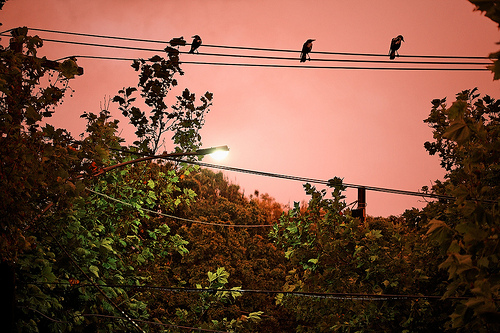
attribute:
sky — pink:
[94, 17, 479, 186]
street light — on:
[101, 144, 229, 171]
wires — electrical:
[226, 44, 262, 66]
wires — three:
[3, 26, 498, 84]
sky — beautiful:
[0, 0, 499, 217]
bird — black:
[387, 33, 404, 60]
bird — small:
[381, 30, 410, 60]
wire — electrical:
[109, 145, 436, 199]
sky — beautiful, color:
[315, 86, 434, 141]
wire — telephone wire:
[222, 25, 499, 85]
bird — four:
[386, 29, 403, 65]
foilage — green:
[196, 258, 246, 301]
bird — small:
[293, 23, 328, 87]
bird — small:
[293, 27, 317, 62]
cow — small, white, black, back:
[225, 142, 303, 183]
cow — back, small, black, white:
[227, 144, 317, 258]